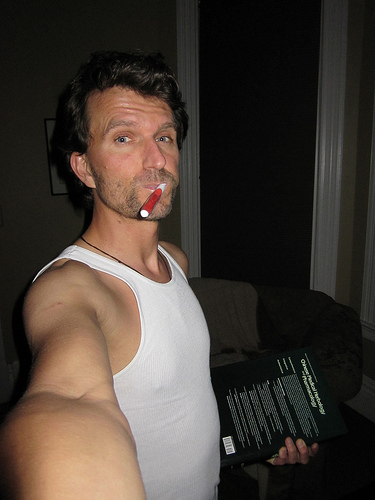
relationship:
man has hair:
[5, 47, 221, 498] [50, 48, 187, 214]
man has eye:
[5, 47, 221, 498] [111, 132, 135, 144]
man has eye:
[5, 47, 221, 498] [155, 134, 178, 144]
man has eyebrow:
[5, 47, 221, 498] [100, 119, 136, 136]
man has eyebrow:
[5, 47, 221, 498] [154, 119, 179, 133]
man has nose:
[5, 47, 221, 498] [143, 138, 168, 170]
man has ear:
[5, 47, 221, 498] [71, 147, 96, 189]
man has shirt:
[5, 47, 221, 498] [34, 246, 226, 499]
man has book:
[5, 47, 221, 498] [210, 342, 352, 467]